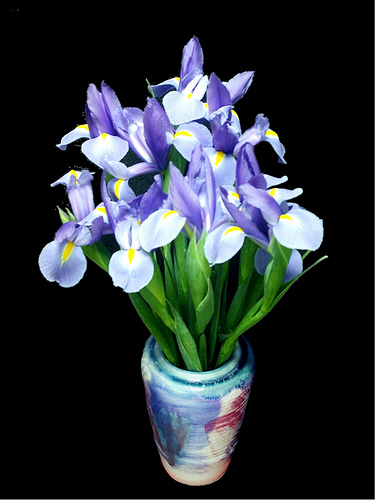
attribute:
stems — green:
[106, 248, 288, 368]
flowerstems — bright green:
[44, 223, 340, 371]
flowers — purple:
[158, 127, 248, 225]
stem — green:
[188, 245, 212, 352]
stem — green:
[164, 275, 243, 384]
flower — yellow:
[118, 241, 139, 268]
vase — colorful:
[138, 328, 264, 488]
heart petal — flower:
[160, 88, 205, 124]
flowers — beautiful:
[54, 99, 285, 330]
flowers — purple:
[18, 76, 336, 361]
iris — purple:
[269, 203, 328, 248]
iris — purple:
[134, 206, 195, 249]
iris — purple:
[107, 242, 153, 293]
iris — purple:
[37, 234, 91, 287]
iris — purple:
[78, 133, 127, 174]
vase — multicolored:
[132, 342, 272, 488]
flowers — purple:
[33, 35, 338, 299]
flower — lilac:
[37, 210, 173, 364]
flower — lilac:
[105, 203, 206, 372]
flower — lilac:
[201, 190, 261, 372]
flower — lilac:
[55, 78, 155, 221]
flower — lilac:
[150, 30, 250, 153]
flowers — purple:
[37, 36, 327, 371]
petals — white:
[34, 181, 336, 305]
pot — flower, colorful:
[132, 332, 256, 489]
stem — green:
[83, 234, 312, 468]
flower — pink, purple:
[43, 39, 329, 350]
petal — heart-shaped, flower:
[161, 89, 207, 125]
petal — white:
[110, 250, 153, 290]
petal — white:
[270, 202, 325, 252]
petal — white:
[202, 224, 244, 267]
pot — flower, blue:
[138, 325, 258, 486]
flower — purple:
[126, 98, 168, 179]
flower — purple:
[227, 142, 275, 204]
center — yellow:
[122, 248, 139, 267]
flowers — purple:
[36, 36, 323, 287]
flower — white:
[105, 249, 154, 293]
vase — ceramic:
[140, 332, 255, 484]